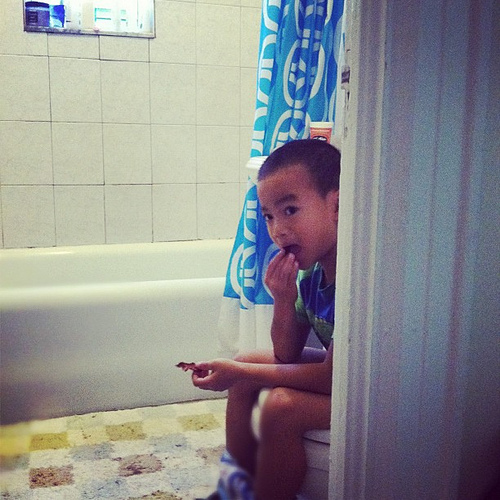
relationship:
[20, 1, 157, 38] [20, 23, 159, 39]
window has ledge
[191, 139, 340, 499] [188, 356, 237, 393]
boy has hand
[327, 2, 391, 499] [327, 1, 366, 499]
door has edge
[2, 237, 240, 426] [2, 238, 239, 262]
tub has edge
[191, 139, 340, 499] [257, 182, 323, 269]
boy has face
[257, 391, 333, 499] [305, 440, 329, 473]
toilet has edge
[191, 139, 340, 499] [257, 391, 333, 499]
boy sitting on toilet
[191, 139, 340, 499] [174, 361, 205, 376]
boy has snack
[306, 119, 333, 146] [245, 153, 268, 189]
cup on top of sink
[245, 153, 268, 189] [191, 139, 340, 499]
sink behind boy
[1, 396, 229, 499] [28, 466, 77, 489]
rug has square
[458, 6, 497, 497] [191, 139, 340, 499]
wall beside boy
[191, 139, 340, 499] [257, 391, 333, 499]
boy on toilet